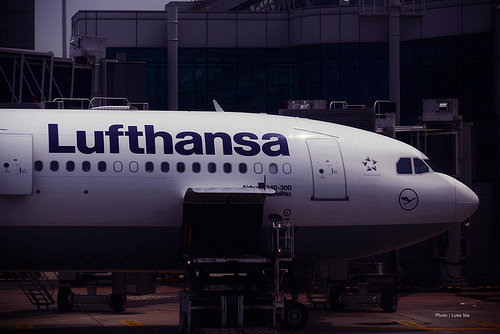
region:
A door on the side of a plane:
[303, 133, 348, 200]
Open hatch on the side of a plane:
[179, 185, 277, 262]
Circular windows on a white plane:
[31, 158, 297, 173]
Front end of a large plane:
[378, 127, 483, 264]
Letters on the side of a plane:
[47, 116, 292, 158]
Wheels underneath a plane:
[279, 293, 307, 330]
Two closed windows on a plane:
[113, 158, 138, 172]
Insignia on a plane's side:
[361, 153, 378, 170]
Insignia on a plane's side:
[398, 186, 417, 210]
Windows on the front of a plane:
[393, 151, 435, 174]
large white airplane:
[5, 90, 482, 247]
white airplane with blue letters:
[21, 105, 483, 242]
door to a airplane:
[296, 135, 365, 232]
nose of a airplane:
[396, 148, 489, 228]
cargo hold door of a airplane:
[175, 176, 300, 281]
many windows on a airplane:
[36, 155, 299, 178]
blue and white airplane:
[26, 109, 473, 231]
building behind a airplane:
[63, 6, 428, 88]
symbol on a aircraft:
[360, 156, 383, 176]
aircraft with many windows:
[23, 110, 470, 256]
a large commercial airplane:
[2, 101, 479, 268]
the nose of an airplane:
[335, 137, 477, 255]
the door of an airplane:
[290, 139, 357, 201]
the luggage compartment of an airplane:
[173, 173, 277, 256]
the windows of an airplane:
[79, 158, 292, 181]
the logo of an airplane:
[42, 118, 289, 162]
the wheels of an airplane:
[267, 290, 314, 320]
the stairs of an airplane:
[23, 270, 63, 309]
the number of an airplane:
[255, 183, 299, 193]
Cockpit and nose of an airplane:
[380, 135, 477, 245]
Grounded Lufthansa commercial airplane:
[0, 102, 480, 302]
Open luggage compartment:
[175, 185, 275, 257]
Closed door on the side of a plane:
[305, 131, 350, 201]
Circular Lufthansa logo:
[356, 151, 381, 176]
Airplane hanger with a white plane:
[1, 0, 496, 330]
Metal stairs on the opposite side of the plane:
[10, 265, 56, 310]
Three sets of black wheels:
[50, 280, 397, 325]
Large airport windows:
[105, 42, 495, 108]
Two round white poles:
[163, 13, 403, 111]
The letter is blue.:
[41, 118, 77, 157]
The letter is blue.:
[75, 125, 106, 165]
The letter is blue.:
[103, 114, 125, 157]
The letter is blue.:
[123, 120, 145, 160]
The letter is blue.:
[143, 118, 175, 168]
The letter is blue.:
[172, 124, 205, 162]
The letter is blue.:
[201, 126, 233, 164]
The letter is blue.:
[231, 126, 263, 163]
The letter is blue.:
[260, 125, 294, 161]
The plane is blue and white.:
[0, 93, 481, 329]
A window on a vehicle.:
[33, 158, 46, 173]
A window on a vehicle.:
[48, 157, 60, 173]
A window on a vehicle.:
[97, 157, 107, 170]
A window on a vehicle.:
[144, 159, 155, 171]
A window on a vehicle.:
[159, 160, 168, 173]